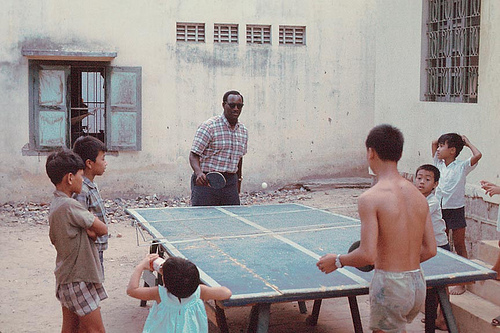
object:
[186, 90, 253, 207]
man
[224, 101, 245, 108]
sunglasses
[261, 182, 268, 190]
ball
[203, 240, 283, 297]
paint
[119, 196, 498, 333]
table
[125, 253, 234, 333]
child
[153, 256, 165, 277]
cup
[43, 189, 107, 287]
shirt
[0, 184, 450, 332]
ground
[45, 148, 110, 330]
boy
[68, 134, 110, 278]
boy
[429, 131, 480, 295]
boy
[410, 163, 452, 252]
boy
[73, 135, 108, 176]
head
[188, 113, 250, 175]
shirt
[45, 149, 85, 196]
head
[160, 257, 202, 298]
head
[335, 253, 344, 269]
silver watch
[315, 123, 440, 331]
boy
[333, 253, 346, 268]
wrist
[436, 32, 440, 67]
bars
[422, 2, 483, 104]
window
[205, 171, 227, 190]
ping-pong paddle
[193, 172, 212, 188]
hand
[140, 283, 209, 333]
dress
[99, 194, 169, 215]
rubble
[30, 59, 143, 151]
window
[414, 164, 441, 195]
head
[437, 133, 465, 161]
head